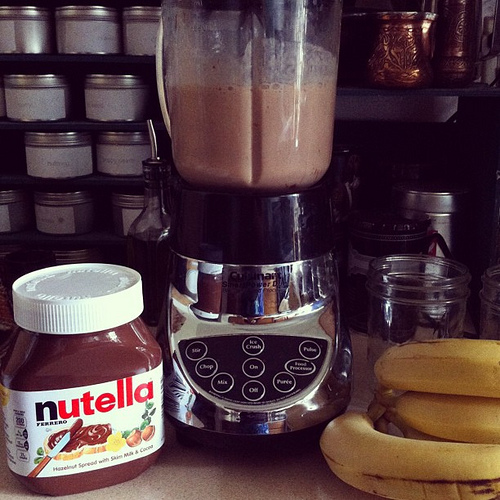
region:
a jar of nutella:
[10, 259, 166, 494]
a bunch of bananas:
[310, 332, 496, 493]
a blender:
[139, 7, 359, 454]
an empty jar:
[362, 243, 469, 334]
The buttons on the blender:
[178, 334, 334, 405]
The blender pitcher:
[150, 6, 339, 204]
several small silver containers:
[10, 5, 122, 238]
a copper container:
[360, 6, 487, 89]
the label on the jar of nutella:
[12, 385, 158, 466]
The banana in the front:
[313, 429, 498, 495]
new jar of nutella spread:
[7, 261, 171, 498]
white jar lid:
[6, 260, 146, 337]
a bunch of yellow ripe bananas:
[316, 335, 498, 498]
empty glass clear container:
[365, 246, 470, 371]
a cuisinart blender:
[144, 3, 354, 448]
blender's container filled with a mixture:
[157, 2, 342, 197]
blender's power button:
[240, 358, 268, 375]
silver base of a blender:
[157, 249, 356, 451]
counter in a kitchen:
[1, 313, 498, 497]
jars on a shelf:
[1, 3, 163, 55]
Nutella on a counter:
[3, 266, 210, 481]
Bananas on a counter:
[350, 334, 497, 497]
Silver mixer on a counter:
[152, 255, 370, 458]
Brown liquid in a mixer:
[153, 51, 362, 261]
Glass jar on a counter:
[357, 253, 487, 394]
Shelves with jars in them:
[2, 53, 184, 178]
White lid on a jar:
[6, 258, 189, 417]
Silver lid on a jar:
[16, 184, 136, 244]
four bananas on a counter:
[361, 335, 480, 499]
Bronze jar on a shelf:
[351, 6, 488, 93]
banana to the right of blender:
[321, 394, 498, 499]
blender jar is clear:
[167, 5, 337, 185]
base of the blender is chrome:
[163, 251, 355, 442]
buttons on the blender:
[184, 335, 322, 400]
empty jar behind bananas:
[362, 257, 474, 339]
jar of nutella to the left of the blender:
[1, 261, 174, 497]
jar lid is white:
[10, 260, 151, 335]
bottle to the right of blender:
[123, 157, 178, 323]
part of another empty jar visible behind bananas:
[480, 271, 499, 341]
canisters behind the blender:
[24, 127, 91, 179]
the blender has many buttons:
[156, 2, 356, 455]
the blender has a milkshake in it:
[166, 72, 338, 194]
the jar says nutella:
[38, 372, 153, 422]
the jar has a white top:
[9, 259, 149, 335]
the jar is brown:
[4, 258, 166, 498]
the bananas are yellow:
[319, 327, 499, 498]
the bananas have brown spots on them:
[322, 448, 499, 498]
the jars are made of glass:
[363, 248, 498, 387]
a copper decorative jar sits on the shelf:
[356, 5, 433, 90]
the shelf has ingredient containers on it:
[0, 2, 200, 297]